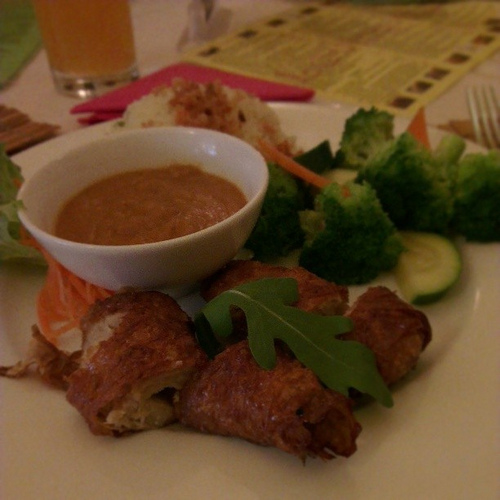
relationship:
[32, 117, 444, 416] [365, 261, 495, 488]
food on plate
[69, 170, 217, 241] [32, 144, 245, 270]
dip in bowl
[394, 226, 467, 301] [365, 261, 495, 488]
cucumber on plate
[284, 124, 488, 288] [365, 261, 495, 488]
vegetables on plate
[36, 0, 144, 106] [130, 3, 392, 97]
glass on table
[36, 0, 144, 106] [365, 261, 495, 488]
glass behind plate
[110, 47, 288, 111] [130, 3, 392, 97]
napkin on table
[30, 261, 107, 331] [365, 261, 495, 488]
carrots on plate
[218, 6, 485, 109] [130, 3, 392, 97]
menu on table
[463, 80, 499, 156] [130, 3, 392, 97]
fork on table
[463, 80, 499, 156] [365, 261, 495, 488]
fork beside plate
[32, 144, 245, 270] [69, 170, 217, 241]
bowl of sauce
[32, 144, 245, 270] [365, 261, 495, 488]
bowl on plate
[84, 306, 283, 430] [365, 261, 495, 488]
dough on plate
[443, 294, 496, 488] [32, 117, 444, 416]
plate of food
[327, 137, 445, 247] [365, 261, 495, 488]
broccoli on plate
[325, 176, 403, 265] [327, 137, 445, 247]
head of broccoli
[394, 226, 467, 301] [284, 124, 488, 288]
cucumber in vegetables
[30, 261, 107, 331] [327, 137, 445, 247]
slices and broccoli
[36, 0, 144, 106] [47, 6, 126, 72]
glass with beverage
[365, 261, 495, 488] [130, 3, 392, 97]
plate on table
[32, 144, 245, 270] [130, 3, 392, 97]
bowl on table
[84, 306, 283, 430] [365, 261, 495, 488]
meat on plate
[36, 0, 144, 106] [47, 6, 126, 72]
glass of juice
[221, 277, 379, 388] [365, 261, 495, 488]
leaf on plate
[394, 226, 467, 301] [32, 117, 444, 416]
slice of food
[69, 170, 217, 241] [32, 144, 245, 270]
sauce in bowl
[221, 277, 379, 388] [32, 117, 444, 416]
leaf on food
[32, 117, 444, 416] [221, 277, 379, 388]
food underneath leaf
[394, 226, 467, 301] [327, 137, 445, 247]
vegetable near broccoli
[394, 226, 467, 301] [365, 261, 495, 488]
zucchini on plate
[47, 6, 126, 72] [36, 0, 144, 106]
drink in glass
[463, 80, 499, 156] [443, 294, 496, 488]
fork by plate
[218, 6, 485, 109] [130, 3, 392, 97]
paper on table